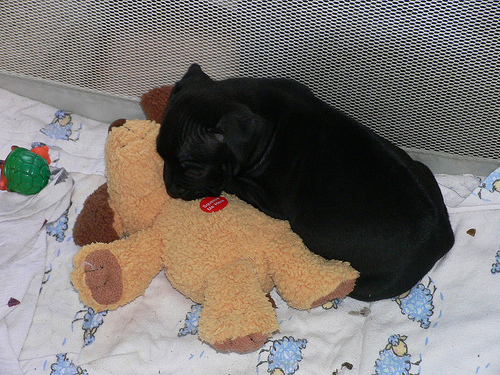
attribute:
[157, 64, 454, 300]
puppy — sleeping, curled up, black, beautiful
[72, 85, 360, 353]
puppy — stuffed, fuzzy, cute, brown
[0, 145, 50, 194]
turtle ball — green, rubber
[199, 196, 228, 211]
tag — red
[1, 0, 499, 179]
cage — grid wire, iron